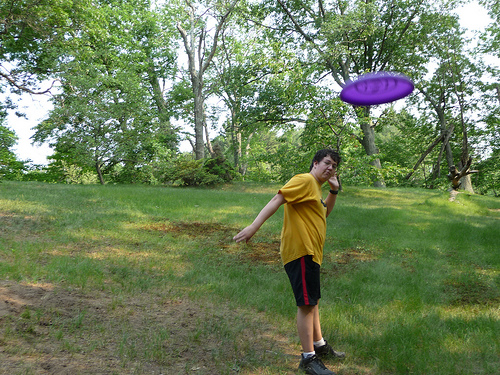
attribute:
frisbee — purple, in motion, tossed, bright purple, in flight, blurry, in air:
[339, 75, 418, 106]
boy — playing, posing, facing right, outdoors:
[229, 149, 348, 374]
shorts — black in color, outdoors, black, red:
[284, 256, 322, 309]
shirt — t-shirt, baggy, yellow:
[279, 173, 325, 265]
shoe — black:
[299, 352, 331, 375]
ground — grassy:
[5, 181, 499, 373]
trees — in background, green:
[2, 0, 498, 198]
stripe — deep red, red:
[298, 256, 308, 307]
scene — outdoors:
[1, 0, 499, 375]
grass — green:
[4, 183, 498, 374]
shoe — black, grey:
[315, 342, 345, 361]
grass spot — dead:
[4, 280, 323, 374]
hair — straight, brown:
[307, 149, 343, 170]